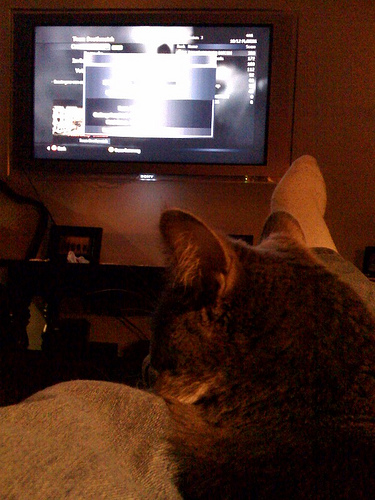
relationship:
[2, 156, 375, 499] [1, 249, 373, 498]
person wears jeans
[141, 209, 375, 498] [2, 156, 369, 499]
animal on person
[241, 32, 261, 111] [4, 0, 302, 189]
numbers on screen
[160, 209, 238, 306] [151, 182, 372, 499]
ear of a cat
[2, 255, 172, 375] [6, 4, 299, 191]
stand under tv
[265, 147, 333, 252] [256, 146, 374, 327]
foot on person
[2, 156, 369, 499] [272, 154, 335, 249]
person wearing a sock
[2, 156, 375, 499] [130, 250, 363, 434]
person wearing jeans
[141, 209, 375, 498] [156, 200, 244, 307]
animal has ear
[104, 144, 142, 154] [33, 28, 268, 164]
button on screen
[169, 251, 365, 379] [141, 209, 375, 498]
head on animal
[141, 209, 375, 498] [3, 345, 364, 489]
animal on couch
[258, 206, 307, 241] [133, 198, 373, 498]
ear of a cat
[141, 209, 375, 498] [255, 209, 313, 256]
animal has ear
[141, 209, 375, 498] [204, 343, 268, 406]
animal has neck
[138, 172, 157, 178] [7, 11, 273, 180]
logo on tv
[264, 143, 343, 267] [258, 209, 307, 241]
sock near ear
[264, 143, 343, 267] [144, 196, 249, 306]
sock near ear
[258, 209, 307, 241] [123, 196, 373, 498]
ear on animal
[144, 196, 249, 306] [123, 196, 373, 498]
ear on animal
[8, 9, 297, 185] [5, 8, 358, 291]
television on wall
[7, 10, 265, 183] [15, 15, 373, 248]
television on wall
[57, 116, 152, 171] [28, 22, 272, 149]
writing on screen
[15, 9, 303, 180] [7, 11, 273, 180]
frame on tv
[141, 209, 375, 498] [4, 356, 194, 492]
animal sitting lap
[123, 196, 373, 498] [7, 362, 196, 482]
animal relaxing lap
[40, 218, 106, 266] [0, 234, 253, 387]
frame on a table